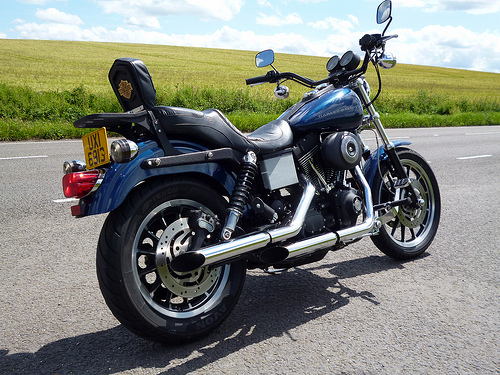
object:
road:
[0, 125, 499, 374]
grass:
[0, 36, 499, 140]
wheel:
[95, 178, 247, 348]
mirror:
[253, 49, 280, 68]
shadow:
[2, 254, 430, 374]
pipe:
[172, 184, 318, 273]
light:
[62, 167, 99, 198]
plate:
[82, 126, 111, 170]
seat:
[109, 58, 292, 154]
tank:
[275, 79, 367, 132]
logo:
[316, 104, 362, 118]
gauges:
[325, 50, 361, 75]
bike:
[63, 1, 440, 346]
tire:
[367, 145, 444, 259]